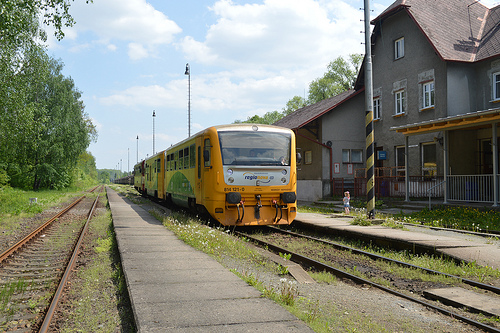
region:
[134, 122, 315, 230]
yellow train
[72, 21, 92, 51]
white clouds in blue sky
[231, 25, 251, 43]
white clouds in blue sky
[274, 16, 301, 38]
white clouds in blue sky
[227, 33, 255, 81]
white clouds in blue sky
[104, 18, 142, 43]
white clouds in blue sky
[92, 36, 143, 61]
white clouds in blue sky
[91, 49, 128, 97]
white clouds in blue sky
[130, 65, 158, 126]
white clouds in blue sky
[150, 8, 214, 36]
white clouds in blue sky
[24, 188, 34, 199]
Small patch of the green grass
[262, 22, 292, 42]
Small patch of the white cloud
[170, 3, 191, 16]
Small patch of the blue sky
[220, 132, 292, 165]
Front window of the train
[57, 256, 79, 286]
Tiny section of the brown train track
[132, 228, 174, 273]
Medium section of the gray walkway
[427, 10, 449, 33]
Small part of the brown roof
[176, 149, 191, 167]
Side windows of the train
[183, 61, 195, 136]
Pole that hovers over the train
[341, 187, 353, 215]
Little girl standing outside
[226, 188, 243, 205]
Black metal fixture on the front of a yellow background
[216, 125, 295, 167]
Large clear glass window on the front of a train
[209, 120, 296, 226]
Yellow painted front of a train car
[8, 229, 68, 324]
Rusted metal train track with rocks and grass in between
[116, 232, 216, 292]
Gray asphalt panels next to a train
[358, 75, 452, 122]
Three windows on the side of a gray building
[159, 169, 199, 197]
Black colored illustration painted on the side of a yellow train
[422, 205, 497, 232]
Yellow flowers in a bed of gray grass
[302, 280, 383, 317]
Pebbles and gray rocks in a heap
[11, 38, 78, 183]
Tall thick tree covered in light green leaves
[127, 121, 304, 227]
The train is yellow.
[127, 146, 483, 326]
The train is on the track.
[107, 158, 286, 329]
The concrete is grey.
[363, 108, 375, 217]
The pole has a caution tape.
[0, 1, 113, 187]
The trees are green.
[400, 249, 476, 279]
The grass is green.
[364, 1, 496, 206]
The house is tall.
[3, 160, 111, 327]
The tracks are straight.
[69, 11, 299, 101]
The sky is cloudy.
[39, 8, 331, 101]
It is in the day time.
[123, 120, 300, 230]
a train on a set of train tracks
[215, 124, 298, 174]
the front window of a train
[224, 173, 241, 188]
the headlight of a train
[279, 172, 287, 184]
the headlight of a train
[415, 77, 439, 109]
the windows of a building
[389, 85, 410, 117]
the windows of a building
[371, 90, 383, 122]
the windows of a building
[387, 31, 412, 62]
a window of a building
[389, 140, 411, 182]
a window of a building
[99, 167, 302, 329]
a wooden sidewalk by train tracks